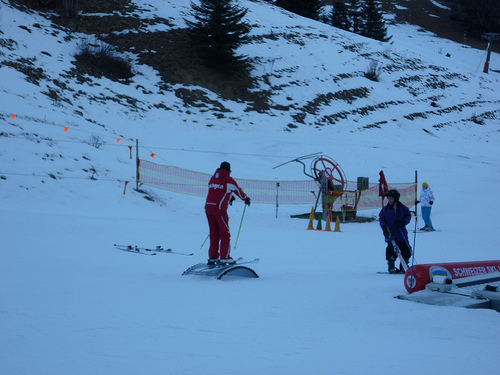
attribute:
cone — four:
[305, 206, 315, 235]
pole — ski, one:
[236, 192, 250, 264]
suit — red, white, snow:
[203, 170, 245, 265]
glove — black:
[242, 191, 253, 208]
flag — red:
[6, 111, 125, 150]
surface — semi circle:
[184, 254, 260, 284]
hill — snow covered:
[12, 20, 484, 202]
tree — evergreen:
[186, 3, 264, 102]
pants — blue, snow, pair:
[418, 201, 435, 232]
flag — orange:
[4, 108, 158, 161]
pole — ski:
[236, 196, 249, 253]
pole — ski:
[193, 195, 228, 251]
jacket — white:
[200, 165, 253, 211]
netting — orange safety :
[138, 147, 428, 241]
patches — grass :
[71, 38, 143, 85]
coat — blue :
[378, 201, 412, 238]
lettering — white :
[207, 180, 227, 189]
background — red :
[205, 168, 228, 201]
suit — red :
[204, 171, 247, 257]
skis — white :
[218, 257, 256, 272]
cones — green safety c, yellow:
[302, 202, 343, 235]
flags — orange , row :
[6, 110, 155, 172]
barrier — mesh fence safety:
[141, 159, 410, 214]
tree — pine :
[139, 6, 279, 103]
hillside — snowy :
[0, 5, 448, 203]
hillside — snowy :
[5, 10, 468, 228]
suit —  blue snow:
[381, 199, 415, 273]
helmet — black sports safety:
[217, 158, 231, 174]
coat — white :
[416, 190, 436, 212]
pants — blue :
[421, 206, 434, 227]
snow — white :
[8, 240, 202, 368]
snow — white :
[51, 266, 322, 357]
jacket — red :
[204, 164, 250, 211]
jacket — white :
[418, 187, 438, 209]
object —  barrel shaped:
[404, 252, 482, 287]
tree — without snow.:
[156, 8, 262, 93]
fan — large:
[310, 148, 353, 209]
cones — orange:
[299, 206, 344, 236]